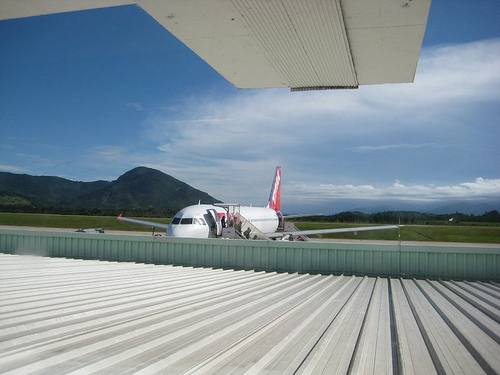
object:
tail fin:
[107, 164, 421, 253]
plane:
[261, 167, 288, 215]